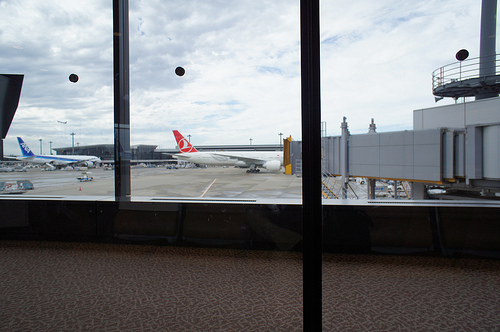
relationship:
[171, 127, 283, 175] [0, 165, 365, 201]
plane on runway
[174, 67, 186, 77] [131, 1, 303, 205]
circle on window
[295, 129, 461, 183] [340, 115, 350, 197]
fence on pole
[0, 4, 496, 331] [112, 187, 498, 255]
glass has reflection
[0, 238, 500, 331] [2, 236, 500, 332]
carpet has pattern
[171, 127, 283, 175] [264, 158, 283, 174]
plane has engine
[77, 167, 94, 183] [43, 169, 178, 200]
car on cement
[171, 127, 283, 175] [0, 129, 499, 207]
plane at airport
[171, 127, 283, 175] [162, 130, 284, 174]
plane at plane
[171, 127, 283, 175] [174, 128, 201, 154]
plane has tail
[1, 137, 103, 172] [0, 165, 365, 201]
airrport on runway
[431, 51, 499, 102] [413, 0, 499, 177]
balcony on building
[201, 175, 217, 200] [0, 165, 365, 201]
line on runway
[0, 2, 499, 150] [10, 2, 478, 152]
sky has clouds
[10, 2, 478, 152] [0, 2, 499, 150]
clouds are in sky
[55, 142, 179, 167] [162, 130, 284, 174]
building at plane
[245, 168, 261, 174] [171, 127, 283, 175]
wheels are under plane